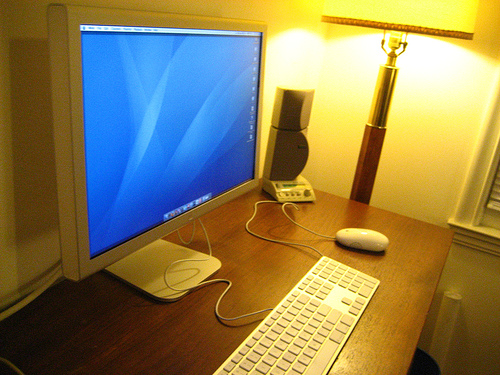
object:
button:
[329, 329, 345, 343]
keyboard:
[209, 253, 382, 374]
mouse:
[335, 228, 389, 252]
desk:
[2, 178, 454, 374]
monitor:
[79, 24, 267, 263]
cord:
[244, 200, 335, 259]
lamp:
[319, 14, 477, 205]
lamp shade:
[316, 13, 475, 40]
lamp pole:
[348, 57, 401, 205]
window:
[448, 96, 500, 255]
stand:
[104, 236, 224, 304]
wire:
[0, 264, 66, 323]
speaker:
[259, 87, 317, 205]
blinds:
[484, 162, 499, 214]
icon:
[249, 134, 253, 140]